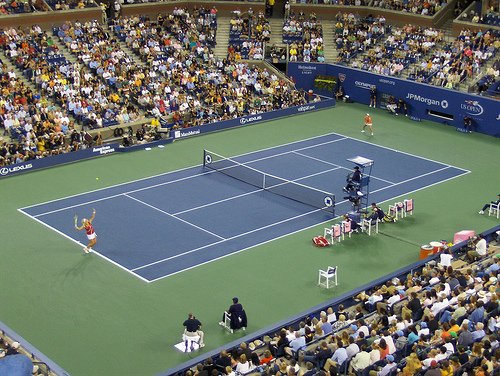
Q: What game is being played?
A: Tennis.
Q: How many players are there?
A: Two.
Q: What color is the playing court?
A: Blue.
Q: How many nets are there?
A: One.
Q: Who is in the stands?
A: The audience.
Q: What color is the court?
A: Blue.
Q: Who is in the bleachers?
A: Spectators.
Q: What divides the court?
A: A net.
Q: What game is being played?
A: Tennis.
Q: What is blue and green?
A: The court.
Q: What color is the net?
A: Black and white.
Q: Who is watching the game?
A: Spectators.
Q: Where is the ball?
A: In the air.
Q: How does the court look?
A: Long and blue.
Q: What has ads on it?
A: A blue sign.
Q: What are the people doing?
A: Watching the players.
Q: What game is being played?
A: Tennis.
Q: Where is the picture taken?
A: A tennis court.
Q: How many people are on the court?
A: Two.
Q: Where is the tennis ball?
A: In the air.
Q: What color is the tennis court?
A: Blue.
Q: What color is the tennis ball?
A: Green.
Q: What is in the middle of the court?
A: A net.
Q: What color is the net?
A: Black and white.